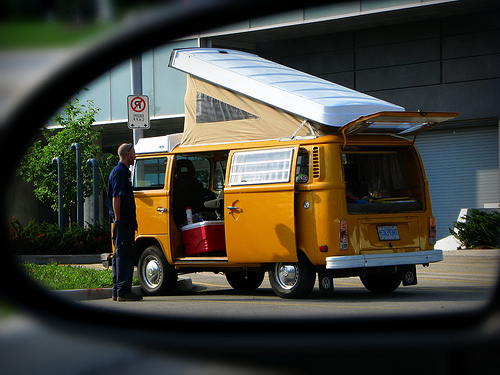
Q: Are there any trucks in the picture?
A: No, there are no trucks.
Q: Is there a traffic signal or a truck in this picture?
A: No, there are no trucks or traffic lights.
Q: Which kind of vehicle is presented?
A: The vehicle is a van.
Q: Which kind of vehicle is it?
A: The vehicle is a van.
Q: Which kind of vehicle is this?
A: This is a van.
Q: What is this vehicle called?
A: This is a van.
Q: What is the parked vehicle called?
A: The vehicle is a van.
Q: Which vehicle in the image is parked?
A: The vehicle is a van.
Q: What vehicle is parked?
A: The vehicle is a van.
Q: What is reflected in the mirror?
A: The van is reflected in the mirror.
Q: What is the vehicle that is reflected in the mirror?
A: The vehicle is a van.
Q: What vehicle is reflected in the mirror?
A: The vehicle is a van.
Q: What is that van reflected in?
A: The van is reflected in the mirror.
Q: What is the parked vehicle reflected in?
A: The van is reflected in the mirror.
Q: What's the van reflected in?
A: The van is reflected in the mirror.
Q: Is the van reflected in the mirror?
A: Yes, the van is reflected in the mirror.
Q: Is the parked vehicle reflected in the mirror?
A: Yes, the van is reflected in the mirror.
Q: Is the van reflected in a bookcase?
A: No, the van is reflected in the mirror.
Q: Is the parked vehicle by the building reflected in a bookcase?
A: No, the van is reflected in the mirror.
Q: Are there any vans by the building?
A: Yes, there is a van by the building.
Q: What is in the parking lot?
A: The van is in the parking lot.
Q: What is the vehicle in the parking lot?
A: The vehicle is a van.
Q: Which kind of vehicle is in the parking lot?
A: The vehicle is a van.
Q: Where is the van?
A: The van is in the parking lot.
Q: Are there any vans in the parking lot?
A: Yes, there is a van in the parking lot.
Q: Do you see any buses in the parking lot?
A: No, there is a van in the parking lot.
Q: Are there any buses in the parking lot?
A: No, there is a van in the parking lot.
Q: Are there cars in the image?
A: No, there are no cars.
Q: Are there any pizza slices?
A: No, there are no pizza slices.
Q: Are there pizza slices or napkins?
A: No, there are no pizza slices or napkins.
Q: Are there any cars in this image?
A: No, there are no cars.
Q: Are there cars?
A: No, there are no cars.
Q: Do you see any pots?
A: No, there are no pots.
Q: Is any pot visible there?
A: No, there are no pots.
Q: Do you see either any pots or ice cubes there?
A: No, there are no pots or ice cubes.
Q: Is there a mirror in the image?
A: Yes, there is a mirror.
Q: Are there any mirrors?
A: Yes, there is a mirror.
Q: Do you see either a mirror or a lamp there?
A: Yes, there is a mirror.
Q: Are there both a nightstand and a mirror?
A: No, there is a mirror but no nightstands.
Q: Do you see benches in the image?
A: No, there are no benches.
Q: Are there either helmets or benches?
A: No, there are no benches or helmets.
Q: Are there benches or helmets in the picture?
A: No, there are no benches or helmets.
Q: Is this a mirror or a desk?
A: This is a mirror.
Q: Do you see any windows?
A: Yes, there is a window.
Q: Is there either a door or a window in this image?
A: Yes, there is a window.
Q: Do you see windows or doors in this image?
A: Yes, there is a window.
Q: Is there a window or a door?
A: Yes, there is a window.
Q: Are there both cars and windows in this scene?
A: No, there is a window but no cars.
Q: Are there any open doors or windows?
A: Yes, there is an open window.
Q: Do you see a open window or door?
A: Yes, there is an open window.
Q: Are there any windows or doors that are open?
A: Yes, the window is open.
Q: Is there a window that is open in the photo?
A: Yes, there is an open window.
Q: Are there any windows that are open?
A: Yes, there is a window that is open.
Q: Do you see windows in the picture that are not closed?
A: Yes, there is a open window.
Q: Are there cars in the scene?
A: No, there are no cars.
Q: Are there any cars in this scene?
A: No, there are no cars.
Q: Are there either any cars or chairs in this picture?
A: No, there are no cars or chairs.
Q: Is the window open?
A: Yes, the window is open.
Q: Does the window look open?
A: Yes, the window is open.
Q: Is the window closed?
A: No, the window is open.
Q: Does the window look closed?
A: No, the window is open.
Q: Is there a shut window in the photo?
A: No, there is a window but it is open.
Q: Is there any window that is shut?
A: No, there is a window but it is open.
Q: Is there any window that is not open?
A: No, there is a window but it is open.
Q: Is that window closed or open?
A: The window is open.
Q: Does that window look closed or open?
A: The window is open.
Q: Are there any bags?
A: No, there are no bags.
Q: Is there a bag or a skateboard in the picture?
A: No, there are no bags or skateboards.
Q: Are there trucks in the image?
A: No, there are no trucks.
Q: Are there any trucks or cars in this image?
A: No, there are no trucks or cars.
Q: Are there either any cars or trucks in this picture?
A: No, there are no trucks or cars.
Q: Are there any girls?
A: No, there are no girls.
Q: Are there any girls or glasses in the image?
A: No, there are no girls or glasses.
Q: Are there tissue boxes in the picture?
A: No, there are no tissue boxes.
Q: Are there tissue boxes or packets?
A: No, there are no tissue boxes or packets.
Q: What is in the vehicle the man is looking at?
A: The cooler is in the van.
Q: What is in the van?
A: The cooler is in the van.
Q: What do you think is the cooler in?
A: The cooler is in the van.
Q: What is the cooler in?
A: The cooler is in the van.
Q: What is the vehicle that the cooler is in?
A: The vehicle is a van.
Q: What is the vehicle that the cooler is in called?
A: The vehicle is a van.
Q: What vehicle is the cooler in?
A: The cooler is in the van.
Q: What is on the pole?
A: The sign is on the pole.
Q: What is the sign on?
A: The sign is on the pole.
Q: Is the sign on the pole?
A: Yes, the sign is on the pole.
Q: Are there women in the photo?
A: No, there are no women.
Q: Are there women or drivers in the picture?
A: No, there are no women or drivers.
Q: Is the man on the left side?
A: Yes, the man is on the left of the image.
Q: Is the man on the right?
A: No, the man is on the left of the image.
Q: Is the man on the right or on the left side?
A: The man is on the left of the image.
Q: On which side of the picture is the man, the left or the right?
A: The man is on the left of the image.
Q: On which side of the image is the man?
A: The man is on the left of the image.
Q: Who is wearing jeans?
A: The man is wearing jeans.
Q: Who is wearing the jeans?
A: The man is wearing jeans.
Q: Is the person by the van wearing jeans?
A: Yes, the man is wearing jeans.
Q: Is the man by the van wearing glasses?
A: No, the man is wearing jeans.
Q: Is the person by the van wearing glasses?
A: No, the man is wearing jeans.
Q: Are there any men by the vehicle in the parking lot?
A: Yes, there is a man by the van.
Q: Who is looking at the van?
A: The man is looking at the van.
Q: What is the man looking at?
A: The man is looking at the van.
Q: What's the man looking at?
A: The man is looking at the van.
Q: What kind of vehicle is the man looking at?
A: The man is looking at the van.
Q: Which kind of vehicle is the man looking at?
A: The man is looking at the van.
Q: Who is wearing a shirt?
A: The man is wearing a shirt.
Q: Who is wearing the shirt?
A: The man is wearing a shirt.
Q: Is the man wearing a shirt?
A: Yes, the man is wearing a shirt.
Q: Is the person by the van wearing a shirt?
A: Yes, the man is wearing a shirt.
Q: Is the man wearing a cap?
A: No, the man is wearing a shirt.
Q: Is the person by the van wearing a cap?
A: No, the man is wearing a shirt.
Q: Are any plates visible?
A: Yes, there is a plate.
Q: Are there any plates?
A: Yes, there is a plate.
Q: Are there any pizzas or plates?
A: Yes, there is a plate.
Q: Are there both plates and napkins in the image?
A: No, there is a plate but no napkins.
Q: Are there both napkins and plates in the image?
A: No, there is a plate but no napkins.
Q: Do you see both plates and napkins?
A: No, there is a plate but no napkins.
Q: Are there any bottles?
A: No, there are no bottles.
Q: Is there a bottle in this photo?
A: No, there are no bottles.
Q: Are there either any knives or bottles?
A: No, there are no bottles or knives.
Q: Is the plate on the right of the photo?
A: Yes, the plate is on the right of the image.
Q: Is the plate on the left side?
A: No, the plate is on the right of the image.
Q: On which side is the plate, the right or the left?
A: The plate is on the right of the image.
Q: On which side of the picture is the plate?
A: The plate is on the right of the image.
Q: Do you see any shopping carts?
A: No, there are no shopping carts.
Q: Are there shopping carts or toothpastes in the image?
A: No, there are no shopping carts or toothpastes.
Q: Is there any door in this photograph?
A: Yes, there is a door.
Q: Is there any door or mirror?
A: Yes, there is a door.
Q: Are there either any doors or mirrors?
A: Yes, there is a door.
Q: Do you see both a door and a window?
A: Yes, there are both a door and a window.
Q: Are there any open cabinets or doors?
A: Yes, there is an open door.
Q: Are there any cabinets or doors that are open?
A: Yes, the door is open.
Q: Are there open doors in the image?
A: Yes, there is an open door.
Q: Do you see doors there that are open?
A: Yes, there is a door that is open.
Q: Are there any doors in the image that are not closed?
A: Yes, there is a open door.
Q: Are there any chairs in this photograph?
A: No, there are no chairs.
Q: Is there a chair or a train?
A: No, there are no chairs or trains.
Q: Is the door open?
A: Yes, the door is open.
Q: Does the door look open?
A: Yes, the door is open.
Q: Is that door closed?
A: No, the door is open.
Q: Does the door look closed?
A: No, the door is open.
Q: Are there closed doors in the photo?
A: No, there is a door but it is open.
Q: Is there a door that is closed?
A: No, there is a door but it is open.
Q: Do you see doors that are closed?
A: No, there is a door but it is open.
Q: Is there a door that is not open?
A: No, there is a door but it is open.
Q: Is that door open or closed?
A: The door is open.